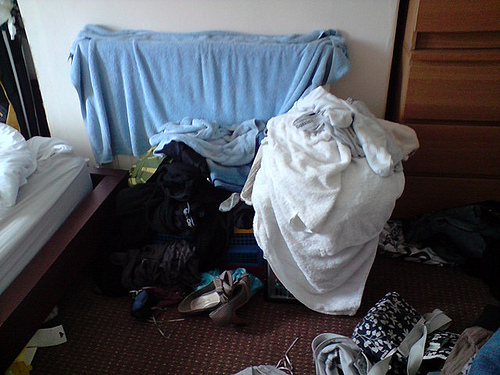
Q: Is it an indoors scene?
A: Yes, it is indoors.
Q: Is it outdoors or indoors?
A: It is indoors.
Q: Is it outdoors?
A: No, it is indoors.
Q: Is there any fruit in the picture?
A: No, there are no fruits.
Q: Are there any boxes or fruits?
A: No, there are no fruits or boxes.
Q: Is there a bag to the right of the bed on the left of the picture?
A: Yes, there are bags to the right of the bed.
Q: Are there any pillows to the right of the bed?
A: No, there are bags to the right of the bed.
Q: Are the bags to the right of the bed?
A: Yes, the bags are to the right of the bed.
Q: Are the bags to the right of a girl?
A: No, the bags are to the right of the bed.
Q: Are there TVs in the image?
A: No, there are no tvs.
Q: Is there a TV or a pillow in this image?
A: No, there are no televisions or pillows.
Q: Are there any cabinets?
A: Yes, there is a cabinet.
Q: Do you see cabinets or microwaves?
A: Yes, there is a cabinet.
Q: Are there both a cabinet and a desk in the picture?
A: No, there is a cabinet but no desks.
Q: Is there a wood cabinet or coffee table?
A: Yes, there is a wood cabinet.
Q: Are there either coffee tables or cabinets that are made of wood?
A: Yes, the cabinet is made of wood.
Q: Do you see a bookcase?
A: No, there are no bookcases.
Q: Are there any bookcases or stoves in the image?
A: No, there are no bookcases or stoves.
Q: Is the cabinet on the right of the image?
A: Yes, the cabinet is on the right of the image.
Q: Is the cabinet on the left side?
A: No, the cabinet is on the right of the image.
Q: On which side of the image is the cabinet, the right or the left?
A: The cabinet is on the right of the image.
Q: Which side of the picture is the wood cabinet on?
A: The cabinet is on the right of the image.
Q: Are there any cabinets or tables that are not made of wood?
A: No, there is a cabinet but it is made of wood.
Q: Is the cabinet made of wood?
A: Yes, the cabinet is made of wood.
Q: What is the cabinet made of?
A: The cabinet is made of wood.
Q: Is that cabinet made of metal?
A: No, the cabinet is made of wood.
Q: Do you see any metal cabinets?
A: No, there is a cabinet but it is made of wood.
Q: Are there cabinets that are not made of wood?
A: No, there is a cabinet but it is made of wood.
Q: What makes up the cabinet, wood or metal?
A: The cabinet is made of wood.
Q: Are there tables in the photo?
A: No, there are no tables.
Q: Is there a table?
A: No, there are no tables.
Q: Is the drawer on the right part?
A: Yes, the drawer is on the right of the image.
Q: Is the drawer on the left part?
A: No, the drawer is on the right of the image.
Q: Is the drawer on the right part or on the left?
A: The drawer is on the right of the image.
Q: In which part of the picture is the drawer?
A: The drawer is on the right of the image.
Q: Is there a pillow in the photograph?
A: No, there are no pillows.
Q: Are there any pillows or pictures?
A: No, there are no pillows or pictures.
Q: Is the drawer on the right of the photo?
A: Yes, the drawer is on the right of the image.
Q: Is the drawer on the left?
A: No, the drawer is on the right of the image.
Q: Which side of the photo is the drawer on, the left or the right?
A: The drawer is on the right of the image.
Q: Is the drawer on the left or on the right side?
A: The drawer is on the right of the image.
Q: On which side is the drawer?
A: The drawer is on the right of the image.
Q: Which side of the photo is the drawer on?
A: The drawer is on the right of the image.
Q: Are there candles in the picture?
A: No, there are no candles.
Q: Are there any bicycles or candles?
A: No, there are no candles or bicycles.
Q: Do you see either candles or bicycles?
A: No, there are no candles or bicycles.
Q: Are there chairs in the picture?
A: No, there are no chairs.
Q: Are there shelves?
A: No, there are no shelves.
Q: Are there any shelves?
A: No, there are no shelves.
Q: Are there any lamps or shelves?
A: No, there are no shelves or lamps.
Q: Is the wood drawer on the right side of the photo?
A: Yes, the drawer is on the right of the image.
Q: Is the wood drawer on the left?
A: No, the drawer is on the right of the image.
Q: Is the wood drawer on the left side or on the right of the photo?
A: The drawer is on the right of the image.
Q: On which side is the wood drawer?
A: The drawer is on the right of the image.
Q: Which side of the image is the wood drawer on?
A: The drawer is on the right of the image.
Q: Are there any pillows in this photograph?
A: No, there are no pillows.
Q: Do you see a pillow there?
A: No, there are no pillows.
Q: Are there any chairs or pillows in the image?
A: No, there are no pillows or chairs.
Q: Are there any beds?
A: Yes, there is a bed.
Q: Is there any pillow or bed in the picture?
A: Yes, there is a bed.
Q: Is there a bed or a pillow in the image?
A: Yes, there is a bed.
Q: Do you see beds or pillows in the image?
A: Yes, there is a bed.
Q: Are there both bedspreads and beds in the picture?
A: No, there is a bed but no bedspreads.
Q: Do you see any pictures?
A: No, there are no pictures.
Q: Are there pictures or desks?
A: No, there are no pictures or desks.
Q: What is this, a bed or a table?
A: This is a bed.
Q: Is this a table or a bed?
A: This is a bed.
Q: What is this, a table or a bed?
A: This is a bed.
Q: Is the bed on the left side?
A: Yes, the bed is on the left of the image.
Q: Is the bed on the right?
A: No, the bed is on the left of the image.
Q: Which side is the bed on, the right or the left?
A: The bed is on the left of the image.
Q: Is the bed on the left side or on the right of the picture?
A: The bed is on the left of the image.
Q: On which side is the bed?
A: The bed is on the left of the image.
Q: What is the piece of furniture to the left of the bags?
A: The piece of furniture is a bed.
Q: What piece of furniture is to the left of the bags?
A: The piece of furniture is a bed.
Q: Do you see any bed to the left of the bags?
A: Yes, there is a bed to the left of the bags.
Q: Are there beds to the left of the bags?
A: Yes, there is a bed to the left of the bags.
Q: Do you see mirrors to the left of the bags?
A: No, there is a bed to the left of the bags.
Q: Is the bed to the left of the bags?
A: Yes, the bed is to the left of the bags.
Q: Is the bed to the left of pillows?
A: No, the bed is to the left of the bags.